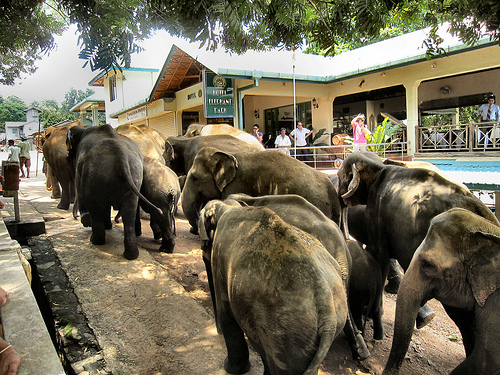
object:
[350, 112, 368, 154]
person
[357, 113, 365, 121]
hand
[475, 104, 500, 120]
shirt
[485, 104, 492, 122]
tie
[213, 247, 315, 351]
stomach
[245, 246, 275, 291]
part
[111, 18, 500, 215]
hotel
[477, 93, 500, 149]
man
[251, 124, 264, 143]
people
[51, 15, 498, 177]
station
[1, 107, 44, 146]
gray building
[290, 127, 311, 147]
shirt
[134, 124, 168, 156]
elephant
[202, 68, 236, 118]
sign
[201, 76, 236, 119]
green background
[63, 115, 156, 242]
elephant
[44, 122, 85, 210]
elephant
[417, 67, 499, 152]
balcony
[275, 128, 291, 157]
man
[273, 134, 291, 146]
shirt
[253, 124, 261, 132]
cell phone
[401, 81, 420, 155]
column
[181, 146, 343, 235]
elehant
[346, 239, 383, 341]
elehant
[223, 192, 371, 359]
elehant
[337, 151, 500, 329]
elehant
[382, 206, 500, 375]
elehant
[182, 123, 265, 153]
elehant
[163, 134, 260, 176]
elehant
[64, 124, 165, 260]
elehant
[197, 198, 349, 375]
elehant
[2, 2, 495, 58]
branches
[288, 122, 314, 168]
man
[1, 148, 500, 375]
street